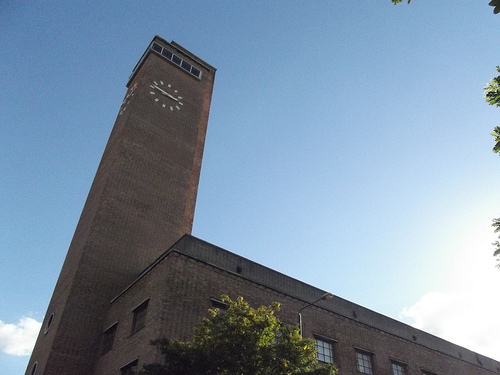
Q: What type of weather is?
A: It is clear.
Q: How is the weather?
A: It is clear.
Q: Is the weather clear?
A: Yes, it is clear.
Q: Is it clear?
A: Yes, it is clear.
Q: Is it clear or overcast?
A: It is clear.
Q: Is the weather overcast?
A: No, it is clear.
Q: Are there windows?
A: Yes, there are windows.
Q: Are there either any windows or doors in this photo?
A: Yes, there are windows.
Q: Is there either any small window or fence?
A: Yes, there are small windows.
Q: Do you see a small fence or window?
A: Yes, there are small windows.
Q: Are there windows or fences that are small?
A: Yes, the windows are small.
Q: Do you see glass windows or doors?
A: Yes, there are glass windows.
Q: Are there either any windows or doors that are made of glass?
A: Yes, the windows are made of glass.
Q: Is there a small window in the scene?
A: Yes, there are small windows.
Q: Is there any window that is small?
A: Yes, there are windows that are small.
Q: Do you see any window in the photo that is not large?
A: Yes, there are small windows.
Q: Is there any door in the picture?
A: No, there are no doors.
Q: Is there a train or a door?
A: No, there are no doors or trains.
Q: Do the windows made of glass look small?
A: Yes, the windows are small.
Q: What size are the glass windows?
A: The windows are small.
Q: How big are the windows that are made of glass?
A: The windows are small.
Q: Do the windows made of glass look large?
A: No, the windows are small.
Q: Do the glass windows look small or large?
A: The windows are small.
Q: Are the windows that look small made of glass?
A: Yes, the windows are made of glass.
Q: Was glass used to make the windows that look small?
A: Yes, the windows are made of glass.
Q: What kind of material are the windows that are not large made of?
A: The windows are made of glass.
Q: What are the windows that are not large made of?
A: The windows are made of glass.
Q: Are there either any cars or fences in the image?
A: No, there are no cars or fences.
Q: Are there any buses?
A: No, there are no buses.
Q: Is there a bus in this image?
A: No, there are no buses.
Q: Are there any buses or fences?
A: No, there are no buses or fences.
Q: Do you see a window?
A: Yes, there are windows.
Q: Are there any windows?
A: Yes, there are windows.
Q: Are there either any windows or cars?
A: Yes, there are windows.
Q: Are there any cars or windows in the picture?
A: Yes, there are windows.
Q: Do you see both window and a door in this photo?
A: No, there are windows but no doors.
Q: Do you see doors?
A: No, there are no doors.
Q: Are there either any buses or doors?
A: No, there are no doors or buses.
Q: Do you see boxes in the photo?
A: No, there are no boxes.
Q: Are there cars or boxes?
A: No, there are no boxes or cars.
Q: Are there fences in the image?
A: No, there are no fences.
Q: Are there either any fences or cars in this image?
A: No, there are no fences or cars.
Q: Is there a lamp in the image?
A: Yes, there is a lamp.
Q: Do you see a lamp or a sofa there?
A: Yes, there is a lamp.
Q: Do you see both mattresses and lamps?
A: No, there is a lamp but no mattresses.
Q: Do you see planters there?
A: No, there are no planters.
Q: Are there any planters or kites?
A: No, there are no planters or kites.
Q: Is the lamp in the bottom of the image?
A: Yes, the lamp is in the bottom of the image.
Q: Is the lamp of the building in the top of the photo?
A: No, the lamp is in the bottom of the image.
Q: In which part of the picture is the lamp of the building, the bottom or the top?
A: The lamp is in the bottom of the image.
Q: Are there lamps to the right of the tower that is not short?
A: Yes, there is a lamp to the right of the tower.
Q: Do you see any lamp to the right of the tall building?
A: Yes, there is a lamp to the right of the tower.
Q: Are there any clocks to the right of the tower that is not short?
A: No, there is a lamp to the right of the tower.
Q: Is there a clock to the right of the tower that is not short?
A: No, there is a lamp to the right of the tower.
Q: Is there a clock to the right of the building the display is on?
A: No, there is a lamp to the right of the tower.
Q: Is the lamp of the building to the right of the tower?
A: Yes, the lamp is to the right of the tower.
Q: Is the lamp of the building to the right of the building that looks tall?
A: Yes, the lamp is to the right of the tower.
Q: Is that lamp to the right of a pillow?
A: No, the lamp is to the right of the tower.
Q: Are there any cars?
A: No, there are no cars.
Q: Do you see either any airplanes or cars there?
A: No, there are no cars or airplanes.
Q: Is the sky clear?
A: Yes, the sky is clear.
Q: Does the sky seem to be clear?
A: Yes, the sky is clear.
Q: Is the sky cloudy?
A: No, the sky is clear.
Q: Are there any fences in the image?
A: No, there are no fences.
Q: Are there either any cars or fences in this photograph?
A: No, there are no fences or cars.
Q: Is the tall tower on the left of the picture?
A: Yes, the tower is on the left of the image.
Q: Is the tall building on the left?
A: Yes, the tower is on the left of the image.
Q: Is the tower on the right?
A: No, the tower is on the left of the image.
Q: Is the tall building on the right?
A: No, the tower is on the left of the image.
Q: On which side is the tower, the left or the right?
A: The tower is on the left of the image.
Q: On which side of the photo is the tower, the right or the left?
A: The tower is on the left of the image.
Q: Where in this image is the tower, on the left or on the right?
A: The tower is on the left of the image.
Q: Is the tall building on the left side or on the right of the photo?
A: The tower is on the left of the image.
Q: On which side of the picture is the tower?
A: The tower is on the left of the image.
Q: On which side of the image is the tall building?
A: The tower is on the left of the image.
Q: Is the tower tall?
A: Yes, the tower is tall.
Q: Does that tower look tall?
A: Yes, the tower is tall.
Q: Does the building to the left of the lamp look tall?
A: Yes, the tower is tall.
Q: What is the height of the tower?
A: The tower is tall.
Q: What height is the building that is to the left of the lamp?
A: The tower is tall.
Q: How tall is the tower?
A: The tower is tall.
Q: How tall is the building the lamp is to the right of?
A: The tower is tall.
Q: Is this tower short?
A: No, the tower is tall.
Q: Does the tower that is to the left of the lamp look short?
A: No, the tower is tall.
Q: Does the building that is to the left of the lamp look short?
A: No, the tower is tall.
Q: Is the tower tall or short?
A: The tower is tall.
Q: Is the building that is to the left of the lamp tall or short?
A: The tower is tall.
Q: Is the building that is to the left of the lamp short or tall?
A: The tower is tall.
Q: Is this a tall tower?
A: Yes, this is a tall tower.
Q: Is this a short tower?
A: No, this is a tall tower.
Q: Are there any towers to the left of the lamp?
A: Yes, there is a tower to the left of the lamp.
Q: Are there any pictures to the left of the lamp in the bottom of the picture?
A: No, there is a tower to the left of the lamp.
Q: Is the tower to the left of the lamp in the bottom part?
A: Yes, the tower is to the left of the lamp.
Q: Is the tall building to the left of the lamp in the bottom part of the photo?
A: Yes, the tower is to the left of the lamp.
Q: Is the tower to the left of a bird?
A: No, the tower is to the left of the lamp.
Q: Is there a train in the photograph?
A: No, there are no trains.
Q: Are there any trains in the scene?
A: No, there are no trains.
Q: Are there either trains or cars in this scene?
A: No, there are no trains or cars.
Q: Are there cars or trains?
A: No, there are no trains or cars.